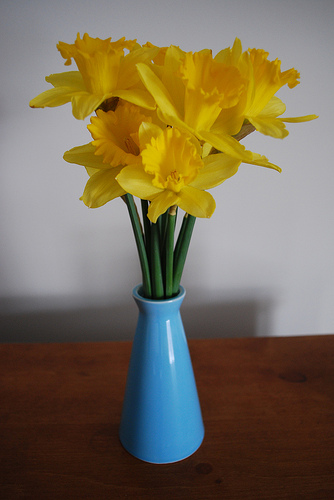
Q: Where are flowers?
A: In a vase.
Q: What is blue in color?
A: The vase.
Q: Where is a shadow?
A: On the wall.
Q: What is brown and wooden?
A: The table.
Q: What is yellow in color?
A: Flowers.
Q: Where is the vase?
A: On a table.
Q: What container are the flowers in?
A: Vase.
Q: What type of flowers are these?
A: Daffodils.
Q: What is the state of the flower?
A: Blooming.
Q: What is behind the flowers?
A: White wall.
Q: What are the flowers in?
A: Blue vase.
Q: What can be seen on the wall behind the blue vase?
A: Shadow.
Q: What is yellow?
A: Flowers.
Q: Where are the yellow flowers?
A: In the blue vase.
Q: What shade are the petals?
A: Bright yellow.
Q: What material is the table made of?
A: Wood.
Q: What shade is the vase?
A: Blue.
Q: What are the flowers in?
A: Vase.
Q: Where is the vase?
A: Table.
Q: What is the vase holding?
A: Flowers.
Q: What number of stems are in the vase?
A: Four.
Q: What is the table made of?
A: Wood.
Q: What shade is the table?
A: Brown.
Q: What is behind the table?
A: Wall.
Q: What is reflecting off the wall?
A: Shadow of table.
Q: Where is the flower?
A: Vase.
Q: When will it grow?
A: Never.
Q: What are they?
A: Flowers.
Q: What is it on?
A: Table.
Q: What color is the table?
A: Brown.